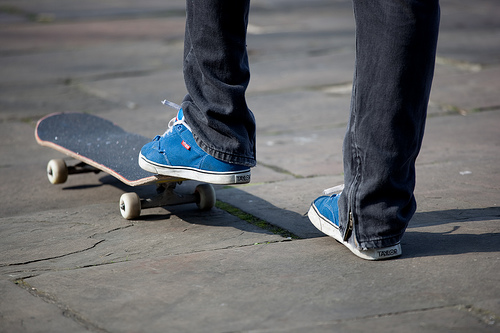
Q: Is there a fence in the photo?
A: No, there are no fences.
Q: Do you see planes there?
A: No, there are no planes.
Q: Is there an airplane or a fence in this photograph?
A: No, there are no airplanes or fences.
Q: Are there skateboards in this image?
A: Yes, there is a skateboard.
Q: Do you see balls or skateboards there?
A: Yes, there is a skateboard.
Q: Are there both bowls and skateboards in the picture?
A: No, there is a skateboard but no bowls.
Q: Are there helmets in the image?
A: No, there are no helmets.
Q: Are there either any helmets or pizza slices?
A: No, there are no helmets or pizza slices.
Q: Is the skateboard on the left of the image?
A: Yes, the skateboard is on the left of the image.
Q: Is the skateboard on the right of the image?
A: No, the skateboard is on the left of the image.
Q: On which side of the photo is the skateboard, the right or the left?
A: The skateboard is on the left of the image.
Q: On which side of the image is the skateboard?
A: The skateboard is on the left of the image.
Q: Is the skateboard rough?
A: Yes, the skateboard is rough.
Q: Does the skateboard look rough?
A: Yes, the skateboard is rough.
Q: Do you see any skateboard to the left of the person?
A: Yes, there is a skateboard to the left of the person.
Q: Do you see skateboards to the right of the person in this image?
A: No, the skateboard is to the left of the person.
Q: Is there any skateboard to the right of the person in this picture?
A: No, the skateboard is to the left of the person.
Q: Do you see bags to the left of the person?
A: No, there is a skateboard to the left of the person.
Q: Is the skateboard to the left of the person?
A: Yes, the skateboard is to the left of the person.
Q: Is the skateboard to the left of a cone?
A: No, the skateboard is to the left of the person.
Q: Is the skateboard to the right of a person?
A: No, the skateboard is to the left of a person.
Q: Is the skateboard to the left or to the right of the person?
A: The skateboard is to the left of the person.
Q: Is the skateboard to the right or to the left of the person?
A: The skateboard is to the left of the person.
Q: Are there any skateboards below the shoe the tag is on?
A: Yes, there is a skateboard below the shoe.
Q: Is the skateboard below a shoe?
A: Yes, the skateboard is below a shoe.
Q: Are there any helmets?
A: No, there are no helmets.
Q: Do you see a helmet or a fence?
A: No, there are no helmets or fences.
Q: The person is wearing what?
A: The person is wearing jeans.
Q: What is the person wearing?
A: The person is wearing jeans.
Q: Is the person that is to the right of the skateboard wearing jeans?
A: Yes, the person is wearing jeans.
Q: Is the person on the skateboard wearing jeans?
A: Yes, the person is wearing jeans.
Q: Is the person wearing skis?
A: No, the person is wearing jeans.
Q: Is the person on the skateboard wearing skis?
A: No, the person is wearing jeans.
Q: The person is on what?
A: The person is on the skateboard.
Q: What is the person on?
A: The person is on the skateboard.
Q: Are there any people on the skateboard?
A: Yes, there is a person on the skateboard.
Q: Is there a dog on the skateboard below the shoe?
A: No, there is a person on the skateboard.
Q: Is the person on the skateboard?
A: Yes, the person is on the skateboard.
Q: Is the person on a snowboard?
A: No, the person is on the skateboard.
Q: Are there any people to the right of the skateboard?
A: Yes, there is a person to the right of the skateboard.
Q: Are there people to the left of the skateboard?
A: No, the person is to the right of the skateboard.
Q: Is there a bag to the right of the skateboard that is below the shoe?
A: No, there is a person to the right of the skateboard.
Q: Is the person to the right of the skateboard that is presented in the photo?
A: Yes, the person is to the right of the skateboard.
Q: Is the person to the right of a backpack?
A: No, the person is to the right of the skateboard.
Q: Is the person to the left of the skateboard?
A: No, the person is to the right of the skateboard.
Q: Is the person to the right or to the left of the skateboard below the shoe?
A: The person is to the right of the skateboard.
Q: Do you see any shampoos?
A: No, there are no shampoos.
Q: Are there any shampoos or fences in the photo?
A: No, there are no shampoos or fences.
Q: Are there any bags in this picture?
A: No, there are no bags.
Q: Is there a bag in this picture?
A: No, there are no bags.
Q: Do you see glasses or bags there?
A: No, there are no bags or glasses.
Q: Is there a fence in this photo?
A: No, there are no fences.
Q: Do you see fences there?
A: No, there are no fences.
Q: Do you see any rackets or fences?
A: No, there are no fences or rackets.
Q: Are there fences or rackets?
A: No, there are no fences or rackets.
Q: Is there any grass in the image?
A: Yes, there is grass.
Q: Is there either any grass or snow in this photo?
A: Yes, there is grass.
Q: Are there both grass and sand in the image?
A: No, there is grass but no sand.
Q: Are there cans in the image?
A: No, there are no cans.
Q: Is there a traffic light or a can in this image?
A: No, there are no cans or traffic lights.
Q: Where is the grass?
A: The grass is on the ground.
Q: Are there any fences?
A: No, there are no fences.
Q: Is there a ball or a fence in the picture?
A: No, there are no fences or balls.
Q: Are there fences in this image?
A: No, there are no fences.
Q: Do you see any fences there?
A: No, there are no fences.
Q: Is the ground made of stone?
A: Yes, the ground is made of stone.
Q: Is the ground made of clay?
A: No, the ground is made of stone.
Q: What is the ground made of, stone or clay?
A: The ground is made of stone.